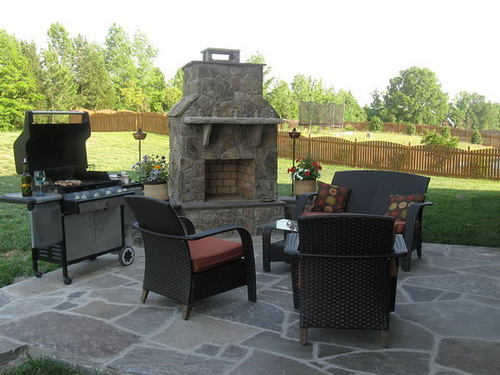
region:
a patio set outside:
[184, 175, 455, 294]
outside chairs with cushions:
[125, 170, 402, 355]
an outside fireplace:
[93, 33, 346, 342]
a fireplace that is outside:
[155, 31, 347, 351]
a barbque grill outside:
[15, 91, 172, 329]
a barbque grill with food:
[7, 89, 149, 257]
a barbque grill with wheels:
[12, 78, 128, 328]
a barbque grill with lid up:
[12, 82, 200, 361]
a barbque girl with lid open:
[3, 80, 136, 315]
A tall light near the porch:
[283, 123, 300, 203]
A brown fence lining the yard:
[321, 124, 493, 179]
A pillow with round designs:
[311, 174, 356, 219]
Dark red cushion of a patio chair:
[176, 225, 246, 270]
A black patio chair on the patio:
[118, 177, 265, 328]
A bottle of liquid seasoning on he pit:
[13, 153, 39, 204]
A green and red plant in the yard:
[281, 143, 327, 210]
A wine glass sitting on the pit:
[30, 164, 51, 201]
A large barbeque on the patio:
[4, 94, 164, 284]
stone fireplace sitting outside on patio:
[157, 41, 288, 254]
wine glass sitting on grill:
[31, 162, 46, 197]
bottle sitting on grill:
[15, 155, 35, 195]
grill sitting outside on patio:
[0, 101, 146, 286]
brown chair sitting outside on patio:
[115, 187, 265, 324]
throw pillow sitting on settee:
[310, 175, 351, 210]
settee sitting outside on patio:
[277, 160, 437, 271]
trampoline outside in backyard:
[295, 94, 350, 139]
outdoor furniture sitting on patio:
[258, 157, 437, 356]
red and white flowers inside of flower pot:
[284, 154, 323, 183]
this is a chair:
[127, 193, 251, 303]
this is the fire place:
[193, 127, 260, 202]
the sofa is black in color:
[309, 216, 386, 322]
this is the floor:
[207, 313, 284, 373]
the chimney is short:
[172, 46, 266, 172]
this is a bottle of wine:
[21, 157, 33, 191]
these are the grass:
[440, 189, 491, 239]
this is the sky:
[300, 21, 387, 67]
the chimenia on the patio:
[154, 35, 295, 223]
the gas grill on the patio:
[5, 98, 152, 290]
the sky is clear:
[164, 0, 497, 53]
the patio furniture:
[117, 151, 440, 343]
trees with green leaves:
[6, 34, 141, 106]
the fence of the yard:
[281, 126, 498, 186]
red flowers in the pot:
[290, 158, 322, 175]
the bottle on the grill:
[16, 161, 41, 197]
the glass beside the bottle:
[34, 170, 46, 192]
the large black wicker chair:
[124, 194, 261, 322]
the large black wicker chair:
[282, 212, 411, 350]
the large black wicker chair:
[260, 170, 433, 282]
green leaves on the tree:
[424, 89, 444, 110]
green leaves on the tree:
[441, 133, 452, 147]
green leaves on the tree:
[473, 99, 496, 126]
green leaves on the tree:
[462, 100, 477, 117]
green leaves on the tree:
[370, 88, 409, 116]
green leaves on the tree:
[334, 88, 366, 118]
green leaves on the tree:
[291, 66, 308, 84]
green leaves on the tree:
[288, 89, 307, 116]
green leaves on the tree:
[263, 88, 285, 109]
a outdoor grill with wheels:
[10, 95, 137, 272]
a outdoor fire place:
[167, 47, 277, 203]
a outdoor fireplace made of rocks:
[147, 46, 297, 231]